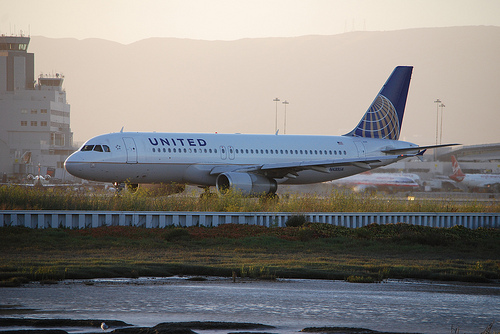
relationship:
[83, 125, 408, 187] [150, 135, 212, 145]
airplane of united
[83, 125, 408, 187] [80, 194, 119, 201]
airplane on tarmac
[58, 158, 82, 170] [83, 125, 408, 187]
nose of airplane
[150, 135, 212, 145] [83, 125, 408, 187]
united on airplane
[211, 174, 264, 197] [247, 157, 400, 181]
engine on wing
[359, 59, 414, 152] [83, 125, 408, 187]
tail of airplane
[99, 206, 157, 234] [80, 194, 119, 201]
fence near tarmac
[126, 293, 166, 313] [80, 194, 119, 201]
pond near tarmac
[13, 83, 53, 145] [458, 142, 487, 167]
control tower of airport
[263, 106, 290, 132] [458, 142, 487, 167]
poles at airport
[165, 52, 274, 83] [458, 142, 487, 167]
mountains near airport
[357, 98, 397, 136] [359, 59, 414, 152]
globe on tail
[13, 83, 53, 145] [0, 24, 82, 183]
control tower on control tower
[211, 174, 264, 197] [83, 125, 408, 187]
engine on airplane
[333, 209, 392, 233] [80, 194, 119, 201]
wall beside tarmac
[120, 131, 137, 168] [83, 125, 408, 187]
door of airplane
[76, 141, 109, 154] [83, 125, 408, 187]
windows on airplane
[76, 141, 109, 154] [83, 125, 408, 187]
windows of airplane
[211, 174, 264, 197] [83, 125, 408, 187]
engine of airplane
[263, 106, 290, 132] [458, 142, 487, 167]
poles on airport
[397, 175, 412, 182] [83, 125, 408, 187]
flag on airplane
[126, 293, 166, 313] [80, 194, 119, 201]
pond on tarmac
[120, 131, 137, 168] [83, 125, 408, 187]
door on airplane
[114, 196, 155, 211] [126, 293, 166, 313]
grass near pond